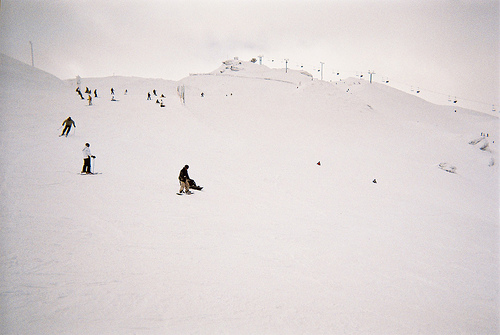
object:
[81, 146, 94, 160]
coat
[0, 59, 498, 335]
slope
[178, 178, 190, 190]
pants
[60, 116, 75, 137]
person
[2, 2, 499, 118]
sky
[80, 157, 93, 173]
bottoms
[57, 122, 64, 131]
pole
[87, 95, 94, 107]
man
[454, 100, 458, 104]
chair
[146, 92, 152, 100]
skier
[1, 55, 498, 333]
mountain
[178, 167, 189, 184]
jacket